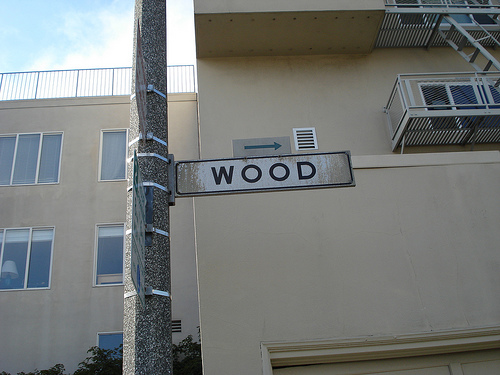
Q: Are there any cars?
A: No, there are no cars.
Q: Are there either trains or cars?
A: No, there are no cars or trains.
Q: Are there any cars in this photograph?
A: No, there are no cars.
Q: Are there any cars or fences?
A: No, there are no cars or fences.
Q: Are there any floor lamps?
A: No, there are no floor lamps.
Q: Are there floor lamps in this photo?
A: No, there are no floor lamps.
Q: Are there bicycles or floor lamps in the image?
A: No, there are no floor lamps or bicycles.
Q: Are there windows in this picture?
A: Yes, there is a window.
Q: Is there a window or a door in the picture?
A: Yes, there is a window.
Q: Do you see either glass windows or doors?
A: Yes, there is a glass window.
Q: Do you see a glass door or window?
A: Yes, there is a glass window.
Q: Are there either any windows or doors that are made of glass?
A: Yes, the window is made of glass.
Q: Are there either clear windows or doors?
A: Yes, there is a clear window.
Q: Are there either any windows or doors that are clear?
A: Yes, the window is clear.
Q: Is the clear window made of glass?
A: Yes, the window is made of glass.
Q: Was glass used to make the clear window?
A: Yes, the window is made of glass.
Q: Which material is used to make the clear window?
A: The window is made of glass.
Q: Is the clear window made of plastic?
A: No, the window is made of glass.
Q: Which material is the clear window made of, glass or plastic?
A: The window is made of glass.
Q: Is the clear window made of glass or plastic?
A: The window is made of glass.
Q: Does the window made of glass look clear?
A: Yes, the window is clear.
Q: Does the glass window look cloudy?
A: No, the window is clear.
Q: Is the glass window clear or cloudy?
A: The window is clear.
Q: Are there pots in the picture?
A: No, there are no pots.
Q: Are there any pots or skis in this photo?
A: No, there are no pots or skis.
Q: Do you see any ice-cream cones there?
A: No, there are no ice-cream cones.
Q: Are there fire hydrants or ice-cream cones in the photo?
A: No, there are no ice-cream cones or fire hydrants.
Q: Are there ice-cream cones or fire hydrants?
A: No, there are no ice-cream cones or fire hydrants.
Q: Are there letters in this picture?
A: Yes, there are letters.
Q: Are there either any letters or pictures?
A: Yes, there are letters.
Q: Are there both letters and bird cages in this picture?
A: No, there are letters but no bird cages.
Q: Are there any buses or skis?
A: No, there are no buses or skis.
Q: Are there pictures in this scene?
A: No, there are no pictures.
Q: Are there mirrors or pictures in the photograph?
A: No, there are no pictures or mirrors.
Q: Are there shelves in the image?
A: No, there are no shelves.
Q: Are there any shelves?
A: No, there are no shelves.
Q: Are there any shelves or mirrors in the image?
A: No, there are no shelves or mirrors.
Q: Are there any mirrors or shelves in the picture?
A: No, there are no shelves or mirrors.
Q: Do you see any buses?
A: No, there are no buses.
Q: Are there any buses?
A: No, there are no buses.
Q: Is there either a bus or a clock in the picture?
A: No, there are no buses or clocks.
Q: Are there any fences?
A: No, there are no fences.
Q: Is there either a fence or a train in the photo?
A: No, there are no fences or trains.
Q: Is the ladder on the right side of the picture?
A: Yes, the ladder is on the right of the image.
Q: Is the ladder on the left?
A: No, the ladder is on the right of the image.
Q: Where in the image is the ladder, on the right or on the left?
A: The ladder is on the right of the image.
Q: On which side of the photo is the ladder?
A: The ladder is on the right of the image.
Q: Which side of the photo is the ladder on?
A: The ladder is on the right of the image.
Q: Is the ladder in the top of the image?
A: Yes, the ladder is in the top of the image.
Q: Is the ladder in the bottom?
A: No, the ladder is in the top of the image.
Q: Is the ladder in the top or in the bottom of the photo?
A: The ladder is in the top of the image.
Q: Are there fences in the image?
A: No, there are no fences.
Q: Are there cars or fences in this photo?
A: No, there are no fences or cars.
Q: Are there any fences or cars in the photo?
A: No, there are no fences or cars.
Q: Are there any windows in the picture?
A: Yes, there are windows.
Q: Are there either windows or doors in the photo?
A: Yes, there are windows.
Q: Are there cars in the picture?
A: No, there are no cars.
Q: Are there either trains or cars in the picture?
A: No, there are no cars or trains.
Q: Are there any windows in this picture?
A: Yes, there is a window.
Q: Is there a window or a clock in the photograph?
A: Yes, there is a window.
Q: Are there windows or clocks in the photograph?
A: Yes, there is a window.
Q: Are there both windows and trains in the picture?
A: No, there is a window but no trains.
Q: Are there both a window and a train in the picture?
A: No, there is a window but no trains.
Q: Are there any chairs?
A: No, there are no chairs.